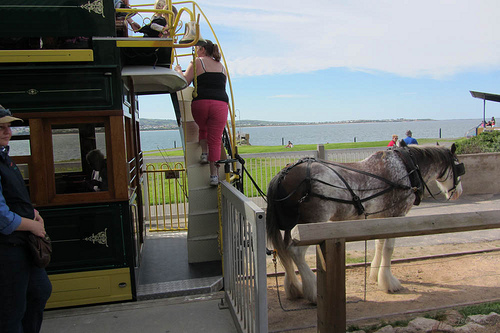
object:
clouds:
[443, 0, 496, 29]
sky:
[132, 0, 500, 123]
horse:
[265, 142, 467, 305]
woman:
[173, 40, 230, 187]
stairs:
[170, 85, 234, 266]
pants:
[1, 236, 53, 333]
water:
[139, 118, 500, 151]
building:
[0, 0, 270, 333]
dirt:
[235, 248, 500, 333]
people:
[403, 130, 419, 145]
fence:
[225, 182, 269, 333]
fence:
[288, 209, 500, 333]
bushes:
[458, 127, 500, 154]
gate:
[141, 163, 190, 233]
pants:
[190, 99, 229, 161]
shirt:
[191, 56, 231, 105]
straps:
[319, 159, 411, 192]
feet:
[376, 274, 403, 294]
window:
[43, 116, 113, 201]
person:
[0, 107, 55, 333]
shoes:
[208, 175, 219, 185]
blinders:
[453, 162, 466, 186]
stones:
[408, 313, 452, 333]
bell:
[179, 20, 207, 46]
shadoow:
[233, 277, 500, 332]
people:
[386, 134, 398, 146]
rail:
[143, 146, 392, 220]